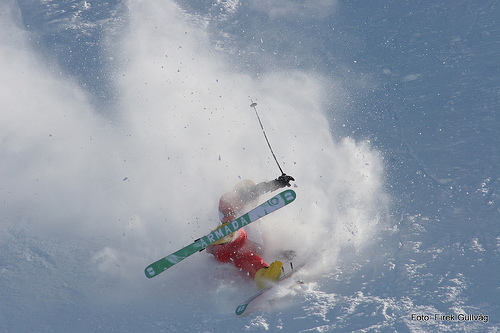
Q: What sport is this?
A: Skiing.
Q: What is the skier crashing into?
A: Snow.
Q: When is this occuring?
A: Daytime.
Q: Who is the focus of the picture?
A: Skier.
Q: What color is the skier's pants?
A: Red.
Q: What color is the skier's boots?
A: Yellow.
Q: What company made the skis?
A: Armada.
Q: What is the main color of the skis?
A: Green.